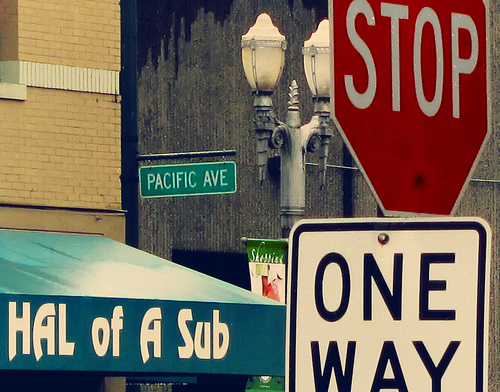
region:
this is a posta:
[132, 156, 244, 200]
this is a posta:
[285, 223, 492, 390]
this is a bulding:
[7, 1, 143, 235]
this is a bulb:
[240, 16, 287, 94]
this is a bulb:
[298, 19, 340, 98]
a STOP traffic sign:
[327, 0, 490, 217]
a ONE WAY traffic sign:
[285, 216, 487, 389]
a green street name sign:
[136, 160, 237, 200]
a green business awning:
[1, 229, 285, 374]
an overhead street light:
[238, 11, 288, 183]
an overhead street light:
[302, 16, 329, 190]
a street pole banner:
[242, 238, 283, 390]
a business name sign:
[2, 297, 284, 372]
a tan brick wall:
[2, 0, 119, 214]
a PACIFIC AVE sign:
[138, 162, 234, 196]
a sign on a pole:
[110, 118, 256, 207]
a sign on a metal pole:
[148, 109, 249, 251]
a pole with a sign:
[164, 128, 239, 228]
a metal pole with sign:
[144, 144, 214, 226]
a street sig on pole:
[153, 140, 245, 226]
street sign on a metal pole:
[157, 138, 257, 188]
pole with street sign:
[151, 130, 228, 196]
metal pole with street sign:
[137, 133, 246, 208]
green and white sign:
[152, 144, 237, 202]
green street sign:
[169, 147, 235, 198]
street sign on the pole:
[127, 153, 252, 203]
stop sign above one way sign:
[329, 5, 493, 219]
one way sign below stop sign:
[276, 198, 496, 389]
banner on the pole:
[239, 225, 293, 312]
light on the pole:
[238, 15, 298, 92]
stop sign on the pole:
[323, 5, 496, 211]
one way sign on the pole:
[278, 207, 495, 382]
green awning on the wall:
[1, 221, 291, 389]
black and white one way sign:
[280, 209, 487, 389]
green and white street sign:
[128, 156, 247, 204]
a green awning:
[1, 223, 293, 381]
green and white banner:
[247, 226, 293, 390]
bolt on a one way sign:
[377, 231, 394, 246]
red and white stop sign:
[326, 2, 498, 224]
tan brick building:
[2, 1, 129, 238]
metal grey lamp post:
[246, 82, 338, 269]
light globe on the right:
[301, 15, 340, 107]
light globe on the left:
[236, 8, 291, 99]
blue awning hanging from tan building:
[3, 3, 283, 374]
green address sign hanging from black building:
[134, 4, 370, 256]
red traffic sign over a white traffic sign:
[286, 2, 493, 386]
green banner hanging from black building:
[232, 235, 284, 390]